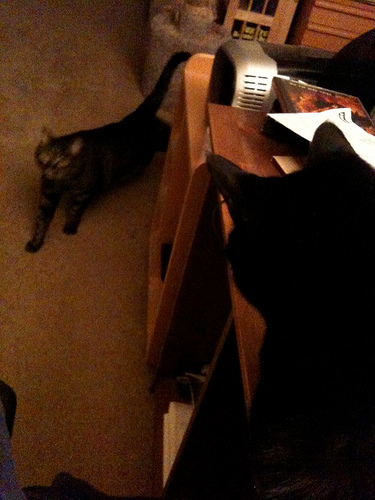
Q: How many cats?
A: 2.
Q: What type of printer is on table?
A: Ink jet.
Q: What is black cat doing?
A: Looking downward.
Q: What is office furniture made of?
A: Wood.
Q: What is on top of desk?
A: Dvd.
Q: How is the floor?
A: Carpeted.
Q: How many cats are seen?
A: Two.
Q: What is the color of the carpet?
A: Brown.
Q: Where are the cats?
A: One on the desk and the other on the carpet.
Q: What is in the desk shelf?
A: Some document papers.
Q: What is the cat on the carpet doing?
A: Stretching.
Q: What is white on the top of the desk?
A: A letter.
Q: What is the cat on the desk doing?
A: Looking at the cat on the carpet.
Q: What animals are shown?
A: Cats.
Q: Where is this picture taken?
A: A living room.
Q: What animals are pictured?
A: Cats.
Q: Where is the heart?
A: Behind cat.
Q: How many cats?
A: Two.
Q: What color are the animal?
A: Black.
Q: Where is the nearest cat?
A: On counter.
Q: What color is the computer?
A: Silver.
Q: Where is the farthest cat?
A: On carpet.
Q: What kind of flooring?
A: Carpet.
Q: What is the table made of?
A: Wood.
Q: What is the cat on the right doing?
A: Looking at the cat on the floor.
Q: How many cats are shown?
A: Two.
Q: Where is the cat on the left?
A: On the floor.